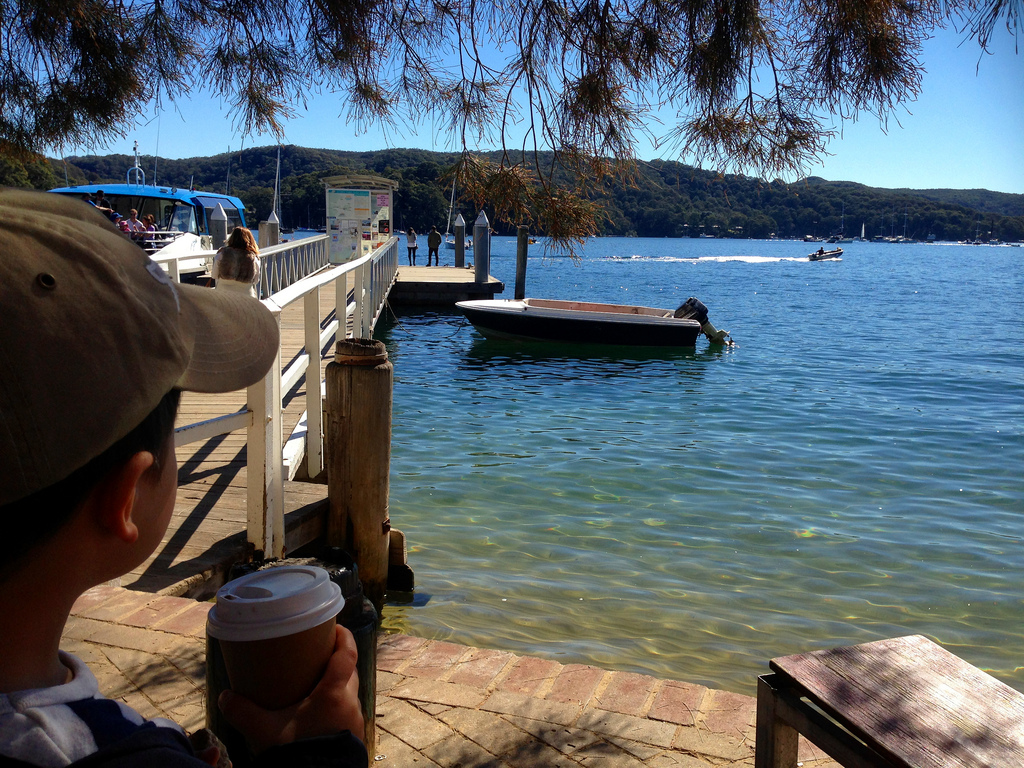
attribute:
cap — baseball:
[1, 190, 287, 481]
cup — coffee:
[212, 537, 358, 722]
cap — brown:
[0, 217, 296, 480]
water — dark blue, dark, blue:
[418, 231, 1020, 608]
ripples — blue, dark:
[785, 381, 921, 459]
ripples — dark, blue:
[850, 283, 961, 373]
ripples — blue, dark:
[481, 426, 540, 471]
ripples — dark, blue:
[626, 359, 794, 424]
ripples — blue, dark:
[472, 364, 625, 445]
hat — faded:
[11, 217, 269, 484]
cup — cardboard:
[204, 565, 350, 755]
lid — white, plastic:
[199, 568, 335, 645]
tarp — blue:
[65, 185, 259, 227]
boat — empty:
[482, 283, 718, 366]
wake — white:
[607, 249, 784, 268]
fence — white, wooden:
[162, 198, 403, 581]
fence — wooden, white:
[162, 243, 315, 308]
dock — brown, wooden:
[136, 265, 381, 598]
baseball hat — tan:
[2, 193, 278, 503]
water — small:
[456, 243, 997, 681]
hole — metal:
[26, 262, 65, 304]